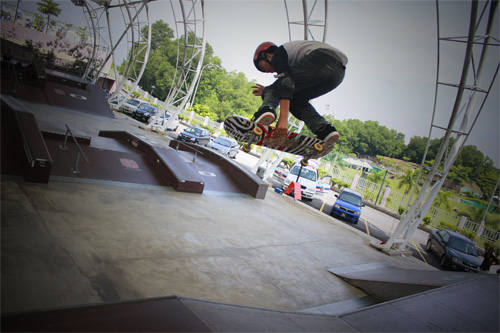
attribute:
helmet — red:
[249, 39, 272, 64]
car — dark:
[425, 227, 482, 272]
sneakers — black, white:
[249, 109, 340, 149]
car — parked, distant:
[424, 224, 482, 276]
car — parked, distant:
[331, 183, 361, 223]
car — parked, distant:
[283, 160, 318, 203]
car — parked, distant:
[206, 134, 238, 161]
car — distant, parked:
[178, 124, 210, 147]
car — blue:
[331, 184, 371, 225]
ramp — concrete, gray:
[52, 259, 499, 331]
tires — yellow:
[303, 139, 337, 160]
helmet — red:
[249, 36, 280, 76]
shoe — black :
[318, 125, 338, 146]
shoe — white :
[255, 109, 274, 127]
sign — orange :
[284, 180, 304, 203]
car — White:
[279, 179, 346, 207]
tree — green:
[120, 18, 221, 115]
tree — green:
[198, 69, 265, 122]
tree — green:
[306, 113, 349, 151]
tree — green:
[349, 118, 369, 154]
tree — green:
[364, 119, 405, 159]